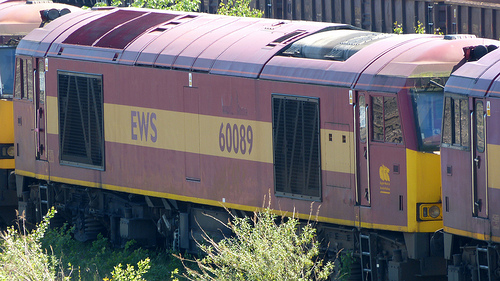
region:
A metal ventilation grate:
[270, 93, 322, 201]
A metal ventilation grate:
[52, 70, 105, 175]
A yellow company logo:
[379, 164, 391, 183]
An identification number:
[217, 119, 252, 155]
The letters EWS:
[127, 107, 157, 142]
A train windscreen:
[440, 95, 470, 147]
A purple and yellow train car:
[10, 2, 497, 232]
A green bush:
[168, 190, 330, 280]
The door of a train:
[469, 97, 488, 218]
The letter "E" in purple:
[130, 107, 139, 138]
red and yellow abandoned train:
[1, 2, 499, 268]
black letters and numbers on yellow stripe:
[106, 105, 271, 155]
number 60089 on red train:
[215, 118, 260, 153]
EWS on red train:
[129, 110, 166, 145]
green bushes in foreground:
[4, 185, 344, 275]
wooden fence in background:
[99, 0, 495, 36]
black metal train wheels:
[13, 176, 486, 278]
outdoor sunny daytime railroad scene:
[3, 2, 497, 274]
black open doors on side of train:
[41, 65, 321, 207]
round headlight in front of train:
[416, 198, 443, 222]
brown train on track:
[341, 1, 462, 24]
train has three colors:
[340, 128, 439, 225]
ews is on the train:
[125, 103, 161, 148]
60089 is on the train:
[215, 116, 262, 156]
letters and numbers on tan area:
[121, 106, 258, 158]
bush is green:
[190, 212, 320, 275]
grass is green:
[81, 240, 128, 266]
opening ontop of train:
[61, 6, 178, 49]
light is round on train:
[415, 200, 443, 220]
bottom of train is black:
[48, 196, 183, 246]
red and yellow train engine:
[12, 7, 460, 265]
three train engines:
[3, 3, 493, 255]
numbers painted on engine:
[206, 111, 259, 163]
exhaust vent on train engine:
[43, 63, 134, 175]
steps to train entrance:
[348, 205, 383, 276]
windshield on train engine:
[399, 63, 448, 162]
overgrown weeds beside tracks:
[11, 191, 326, 275]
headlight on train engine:
[417, 183, 448, 226]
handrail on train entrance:
[29, 96, 54, 170]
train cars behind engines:
[259, 2, 497, 48]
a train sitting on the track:
[2, 0, 469, 277]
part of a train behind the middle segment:
[418, 44, 498, 276]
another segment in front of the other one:
[0, 2, 21, 199]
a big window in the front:
[410, 89, 446, 166]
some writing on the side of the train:
[126, 105, 276, 173]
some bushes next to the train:
[0, 221, 310, 279]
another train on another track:
[229, 0, 489, 45]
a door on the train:
[273, 97, 319, 202]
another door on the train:
[56, 70, 103, 166]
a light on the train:
[418, 202, 438, 219]